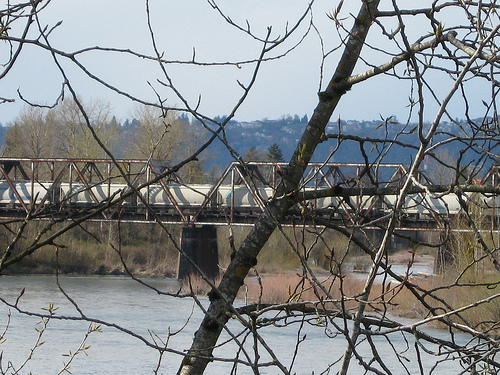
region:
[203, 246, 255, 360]
There is a dark brown trunk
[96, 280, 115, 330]
There is a light brown river here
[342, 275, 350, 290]
There is light vegetation here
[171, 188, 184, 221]
There is a white train here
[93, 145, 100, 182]
There is some silver girding here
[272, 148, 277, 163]
There is an evergreen tree here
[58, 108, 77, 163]
There is a tree visible here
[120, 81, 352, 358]
This photo was taken in autumn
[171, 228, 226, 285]
Cement base of the metal bridge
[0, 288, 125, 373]
Few green branches coming off a bush in the bottom corner of the image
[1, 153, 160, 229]
Metal railing along the edge of the bridge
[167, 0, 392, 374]
Main branch of a gray-brown tree in the foreground of the image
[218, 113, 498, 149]
Buildings along the top of the hill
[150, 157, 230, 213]
Triangular gap in the fence along the bridge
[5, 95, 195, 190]
Sparse light green trees behind the bridge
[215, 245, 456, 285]
Short section of stream traveling away from the camera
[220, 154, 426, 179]
Top of the metal railing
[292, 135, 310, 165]
Green sprout coming out of the tree branch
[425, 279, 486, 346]
small skinny tree branch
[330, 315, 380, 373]
small skinny tree branch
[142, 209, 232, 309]
small skinny tree branch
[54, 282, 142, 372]
small skinny tree branch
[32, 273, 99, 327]
small skinny tree branch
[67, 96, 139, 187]
small skinny tree branch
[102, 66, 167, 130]
small skinny tree branch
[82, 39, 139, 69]
small skinny tree branch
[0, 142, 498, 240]
white metal bridge over water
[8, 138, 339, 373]
water under metal bridge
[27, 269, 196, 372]
water in a river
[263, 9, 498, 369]
a leafless tree branch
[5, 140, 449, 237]
a bridge for a train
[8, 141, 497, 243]
train cars on a bridge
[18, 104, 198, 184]
trees beyond the bridge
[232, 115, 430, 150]
buildings on the distant hill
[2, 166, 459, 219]
white train cars on a bridge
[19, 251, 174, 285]
the bank of a river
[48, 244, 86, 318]
a twig on a tree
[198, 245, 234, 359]
bark on a branch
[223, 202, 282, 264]
a skinny trunk of a tree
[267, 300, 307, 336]
a bunch of empty sticks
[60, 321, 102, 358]
a bunch of baby leaves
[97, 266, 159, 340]
the water of a river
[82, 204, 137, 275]
the stone part of a bridge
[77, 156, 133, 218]
the railing of a bridge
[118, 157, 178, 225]
train tracks that are on a bridge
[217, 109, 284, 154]
a bunch of trees on the mountain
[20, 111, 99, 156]
a lot of yellow leaves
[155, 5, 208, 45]
a bunch of clouds in the sky